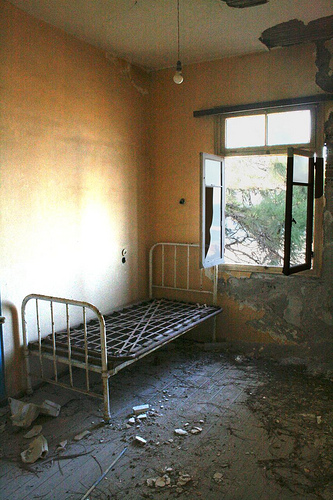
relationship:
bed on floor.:
[21, 238, 223, 418] [163, 383, 281, 456]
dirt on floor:
[229, 361, 320, 443] [144, 411, 226, 474]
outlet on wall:
[121, 247, 128, 263] [0, 1, 150, 406]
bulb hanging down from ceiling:
[173, 60, 184, 84] [7, 0, 330, 72]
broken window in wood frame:
[200, 155, 221, 264] [198, 151, 224, 269]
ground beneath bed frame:
[1, 338, 332, 496] [20, 240, 222, 422]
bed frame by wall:
[19, 242, 218, 423] [0, 1, 150, 406]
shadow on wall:
[106, 148, 162, 223] [4, 103, 164, 235]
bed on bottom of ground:
[21, 238, 223, 418] [1, 342, 333, 500]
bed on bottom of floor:
[23, 262, 226, 401] [4, 344, 321, 495]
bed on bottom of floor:
[21, 238, 223, 418] [150, 372, 266, 468]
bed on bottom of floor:
[21, 238, 223, 418] [97, 353, 332, 499]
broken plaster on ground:
[117, 390, 224, 488] [1, 342, 333, 500]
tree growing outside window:
[223, 188, 309, 266] [197, 104, 320, 278]